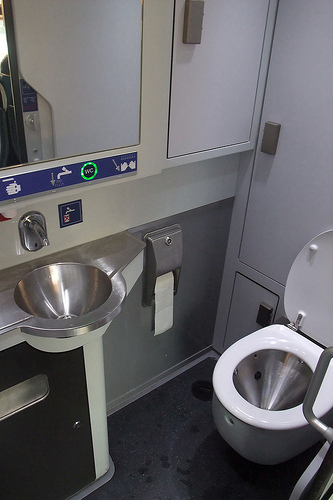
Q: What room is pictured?
A: Bathroom.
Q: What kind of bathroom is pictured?
A: Airline bathroom.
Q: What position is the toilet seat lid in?
A: Up.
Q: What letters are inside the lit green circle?
A: WC.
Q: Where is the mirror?
A: Above the sink.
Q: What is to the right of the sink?
A: Toilet paper dispenser.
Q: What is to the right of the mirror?
A: A cabinet.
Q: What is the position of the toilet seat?
A: Down.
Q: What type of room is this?
A: A restroom.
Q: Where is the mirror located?
A: Above the sink.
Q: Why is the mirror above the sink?
A: To see your face while washing.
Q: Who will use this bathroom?
A: A passenger.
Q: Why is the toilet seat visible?
A: The lid is open.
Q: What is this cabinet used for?
A: Storage.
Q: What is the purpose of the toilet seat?
A: To sit on.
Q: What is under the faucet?
A: The sink.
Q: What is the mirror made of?
A: Glass.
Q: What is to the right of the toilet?
A: Toilet paper.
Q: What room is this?
A: Bathroom.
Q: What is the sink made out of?
A: Stainless steel.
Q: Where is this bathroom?
A: On an airplane.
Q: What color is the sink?
A: Grey.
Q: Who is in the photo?
A: Nobody.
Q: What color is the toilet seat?
A: White.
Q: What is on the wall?
A: Mirrors.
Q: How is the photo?
A: Clear.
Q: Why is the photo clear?
A: Its during the day.